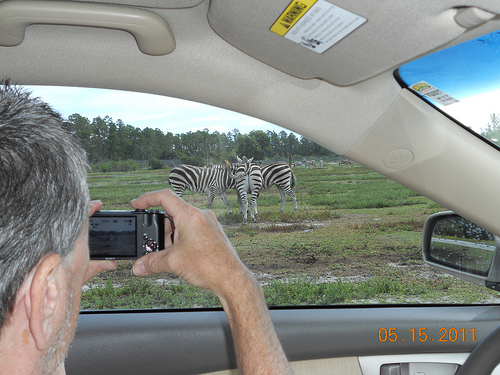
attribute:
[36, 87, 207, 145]
man — taking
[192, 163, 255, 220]
zebra — black, three, backside, group, standing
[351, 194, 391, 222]
grass — green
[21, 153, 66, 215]
hair — brown, grey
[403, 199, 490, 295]
mirror — attached, view, side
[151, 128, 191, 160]
tree — tall, line, growing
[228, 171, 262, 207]
stripe — black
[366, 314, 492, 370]
date — printed, orange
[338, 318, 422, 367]
interior — grey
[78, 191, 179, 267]
camera — dark, small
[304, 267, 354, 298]
water — puddle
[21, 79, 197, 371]
man — taking, holding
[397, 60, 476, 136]
sticker — windshield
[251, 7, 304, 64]
label — yellow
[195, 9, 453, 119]
visor — sun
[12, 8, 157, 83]
handle — support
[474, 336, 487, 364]
wheel — steering